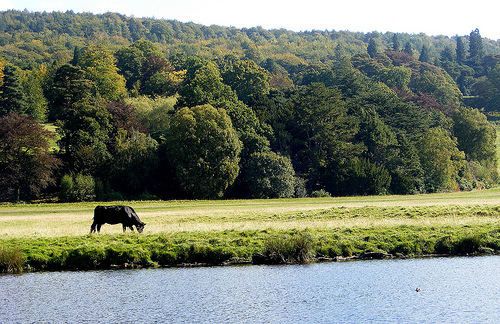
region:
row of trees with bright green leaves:
[43, 45, 455, 190]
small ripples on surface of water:
[53, 267, 265, 321]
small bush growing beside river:
[247, 229, 335, 275]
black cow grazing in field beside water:
[70, 187, 166, 245]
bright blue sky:
[195, 2, 497, 23]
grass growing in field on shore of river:
[202, 197, 492, 228]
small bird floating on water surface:
[400, 278, 436, 303]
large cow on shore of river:
[79, 187, 169, 289]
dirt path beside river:
[263, 213, 423, 228]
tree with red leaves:
[0, 107, 64, 202]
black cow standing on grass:
[81, 197, 143, 239]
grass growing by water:
[92, 232, 231, 267]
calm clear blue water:
[129, 263, 334, 313]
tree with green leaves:
[145, 89, 241, 186]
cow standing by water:
[82, 196, 151, 233]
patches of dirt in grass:
[309, 209, 435, 266]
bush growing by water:
[273, 230, 320, 263]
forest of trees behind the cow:
[31, 40, 301, 191]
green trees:
[20, 40, 320, 190]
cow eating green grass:
[77, 200, 157, 255]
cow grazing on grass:
[79, 203, 157, 230]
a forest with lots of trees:
[3, 3, 498, 191]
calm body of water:
[8, 262, 498, 322]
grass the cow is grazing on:
[5, 192, 498, 247]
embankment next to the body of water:
[5, 230, 490, 255]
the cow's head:
[137, 216, 149, 235]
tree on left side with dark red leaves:
[0, 112, 59, 208]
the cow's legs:
[85, 223, 139, 233]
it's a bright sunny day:
[2, 1, 499, 317]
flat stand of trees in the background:
[5, 8, 498, 55]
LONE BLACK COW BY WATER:
[84, 188, 156, 250]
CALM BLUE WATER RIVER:
[28, 250, 497, 320]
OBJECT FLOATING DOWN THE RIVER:
[400, 275, 434, 297]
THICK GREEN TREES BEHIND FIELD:
[7, 15, 492, 207]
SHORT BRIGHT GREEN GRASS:
[3, 191, 479, 233]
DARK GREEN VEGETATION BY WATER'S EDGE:
[21, 224, 491, 262]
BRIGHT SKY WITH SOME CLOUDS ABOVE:
[24, 7, 496, 70]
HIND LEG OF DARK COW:
[87, 218, 94, 235]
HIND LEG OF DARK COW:
[95, 217, 102, 231]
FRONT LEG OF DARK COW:
[113, 226, 128, 236]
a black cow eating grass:
[88, 205, 145, 235]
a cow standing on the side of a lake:
[87, 204, 146, 234]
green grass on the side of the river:
[0, 232, 497, 269]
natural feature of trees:
[0, 7, 497, 197]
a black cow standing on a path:
[0, 202, 497, 232]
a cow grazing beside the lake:
[87, 204, 145, 233]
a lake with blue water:
[0, 274, 496, 321]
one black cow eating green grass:
[1, 205, 498, 322]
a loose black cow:
[2, 205, 499, 322]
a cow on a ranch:
[2, 202, 498, 322]